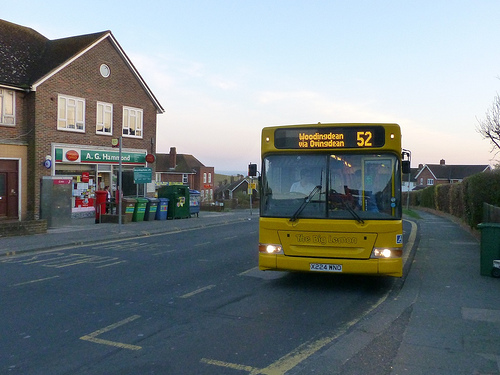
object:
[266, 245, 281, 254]
light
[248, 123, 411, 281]
bus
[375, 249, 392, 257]
light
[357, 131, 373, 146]
number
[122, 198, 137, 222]
trash bin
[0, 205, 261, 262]
sidewalk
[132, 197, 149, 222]
trash bin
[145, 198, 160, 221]
trash bin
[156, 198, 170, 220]
trash bin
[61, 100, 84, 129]
window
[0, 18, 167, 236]
building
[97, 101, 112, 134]
window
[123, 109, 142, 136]
window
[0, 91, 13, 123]
window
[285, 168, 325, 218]
wiper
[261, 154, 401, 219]
windshield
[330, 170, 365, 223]
wiper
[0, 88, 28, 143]
wall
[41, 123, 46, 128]
brick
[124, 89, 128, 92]
brick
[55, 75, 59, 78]
brick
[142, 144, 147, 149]
brick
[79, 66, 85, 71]
brick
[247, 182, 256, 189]
sign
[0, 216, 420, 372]
road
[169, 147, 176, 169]
chimney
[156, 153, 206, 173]
roof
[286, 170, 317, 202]
driver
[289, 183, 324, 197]
shirt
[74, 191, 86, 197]
flyer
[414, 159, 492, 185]
building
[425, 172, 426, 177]
brick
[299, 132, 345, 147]
name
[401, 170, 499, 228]
hedge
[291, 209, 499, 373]
sidewalk